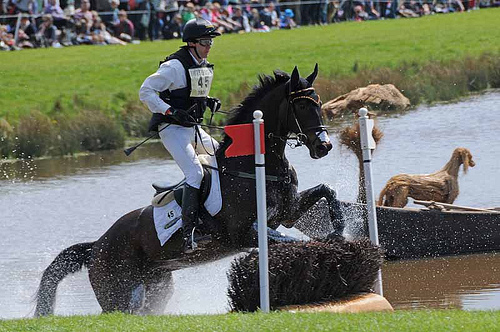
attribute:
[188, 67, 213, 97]
bib — white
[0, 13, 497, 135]
field — grassy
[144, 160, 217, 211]
saddle — black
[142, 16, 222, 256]
man — wearing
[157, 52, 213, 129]
vest — black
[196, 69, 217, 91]
number sign — white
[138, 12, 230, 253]
man — riding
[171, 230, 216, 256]
boot — black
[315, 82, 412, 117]
rock — large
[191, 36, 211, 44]
goggles — safety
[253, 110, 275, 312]
pole — white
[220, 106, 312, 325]
flag — red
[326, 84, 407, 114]
rock — brown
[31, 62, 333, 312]
horse — black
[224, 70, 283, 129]
hair — black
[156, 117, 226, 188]
pants — white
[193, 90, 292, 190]
flag — red 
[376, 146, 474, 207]
dog — wet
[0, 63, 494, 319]
water — brown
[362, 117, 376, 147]
flag — white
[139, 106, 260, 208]
pants — white 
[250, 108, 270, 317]
pole — white